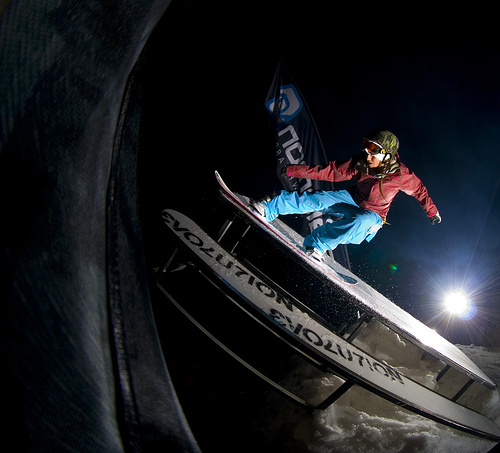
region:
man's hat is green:
[340, 115, 411, 173]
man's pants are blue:
[240, 166, 405, 256]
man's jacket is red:
[267, 131, 473, 226]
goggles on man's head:
[365, 135, 395, 157]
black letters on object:
[156, 182, 418, 412]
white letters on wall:
[275, 117, 331, 249]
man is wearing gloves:
[267, 140, 454, 235]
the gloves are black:
[261, 155, 457, 250]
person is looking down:
[330, 120, 432, 225]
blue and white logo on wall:
[257, 61, 300, 123]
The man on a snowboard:
[208, 159, 365, 299]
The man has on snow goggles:
[354, 137, 392, 162]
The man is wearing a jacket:
[288, 155, 438, 222]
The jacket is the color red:
[316, 165, 409, 202]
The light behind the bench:
[434, 265, 476, 330]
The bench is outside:
[188, 203, 490, 430]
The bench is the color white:
[180, 218, 452, 407]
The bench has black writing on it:
[167, 216, 425, 403]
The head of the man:
[358, 125, 410, 177]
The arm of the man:
[406, 167, 443, 228]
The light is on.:
[428, 274, 479, 314]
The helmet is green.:
[372, 125, 407, 155]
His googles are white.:
[357, 134, 392, 162]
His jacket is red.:
[295, 141, 436, 207]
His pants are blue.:
[267, 175, 388, 250]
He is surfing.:
[251, 123, 446, 276]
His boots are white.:
[238, 185, 333, 272]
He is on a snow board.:
[205, 166, 497, 391]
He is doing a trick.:
[122, 72, 469, 294]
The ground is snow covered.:
[307, 311, 483, 452]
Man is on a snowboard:
[210, 119, 445, 291]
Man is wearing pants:
[249, 184, 384, 255]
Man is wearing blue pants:
[255, 185, 385, 254]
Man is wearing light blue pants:
[263, 187, 382, 254]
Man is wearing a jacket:
[282, 152, 437, 220]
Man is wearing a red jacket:
[288, 152, 439, 219]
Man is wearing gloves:
[275, 161, 442, 226]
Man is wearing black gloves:
[274, 161, 443, 225]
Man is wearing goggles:
[362, 136, 387, 153]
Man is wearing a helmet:
[369, 127, 402, 158]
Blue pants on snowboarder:
[244, 179, 406, 257]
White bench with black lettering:
[162, 215, 439, 442]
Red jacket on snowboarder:
[274, 165, 461, 230]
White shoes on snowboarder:
[252, 181, 354, 277]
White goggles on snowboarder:
[361, 133, 390, 168]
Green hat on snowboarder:
[355, 125, 405, 163]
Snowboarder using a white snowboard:
[205, 156, 497, 396]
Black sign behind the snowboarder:
[251, 76, 354, 267]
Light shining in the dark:
[429, 260, 499, 342]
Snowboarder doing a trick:
[232, 125, 472, 356]